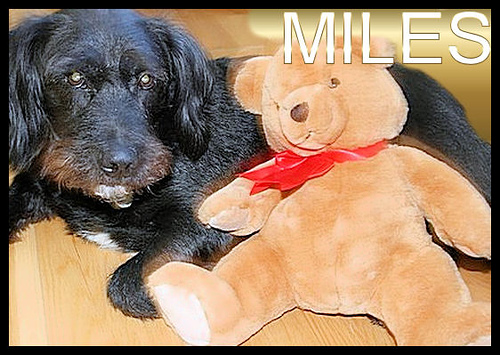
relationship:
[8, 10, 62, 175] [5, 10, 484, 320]
ear of dog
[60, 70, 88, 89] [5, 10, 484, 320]
eye of dog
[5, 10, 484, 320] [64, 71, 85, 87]
dog has an eye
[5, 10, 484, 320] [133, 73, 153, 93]
dog has an eye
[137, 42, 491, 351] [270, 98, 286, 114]
bear has an eye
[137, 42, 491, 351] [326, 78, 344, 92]
bear has an eye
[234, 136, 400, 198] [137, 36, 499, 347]
ribbon on bear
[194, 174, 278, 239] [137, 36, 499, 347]
paw on bear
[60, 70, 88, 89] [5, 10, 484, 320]
eye belonging to dog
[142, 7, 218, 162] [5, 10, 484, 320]
ear belonging to dog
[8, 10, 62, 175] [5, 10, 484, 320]
ear belonging to dog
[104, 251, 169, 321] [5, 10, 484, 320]
paw belonging to dog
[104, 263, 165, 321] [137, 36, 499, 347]
paw belonging to bear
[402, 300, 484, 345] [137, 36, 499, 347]
paw belonging to bear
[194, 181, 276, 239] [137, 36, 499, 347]
paw belonging to bear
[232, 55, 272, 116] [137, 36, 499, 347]
ear belonging to bear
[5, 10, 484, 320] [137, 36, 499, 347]
dog lying next to bear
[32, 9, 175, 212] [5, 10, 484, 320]
head belonging to dog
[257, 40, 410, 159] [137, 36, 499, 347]
head belonging to bear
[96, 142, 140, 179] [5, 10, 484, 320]
nose belonging to dog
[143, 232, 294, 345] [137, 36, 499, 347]
leg belonging to bear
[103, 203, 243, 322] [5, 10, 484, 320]
leg belonging to dog